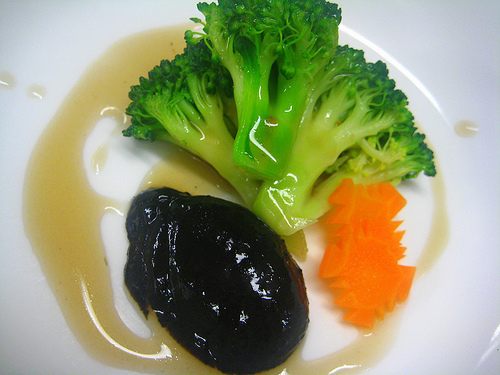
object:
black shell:
[123, 185, 308, 374]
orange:
[352, 217, 392, 284]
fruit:
[125, 187, 309, 375]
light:
[339, 21, 447, 120]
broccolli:
[120, 0, 435, 237]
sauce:
[453, 119, 480, 137]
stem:
[229, 81, 308, 183]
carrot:
[320, 178, 416, 332]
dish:
[0, 0, 500, 375]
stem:
[301, 132, 320, 199]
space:
[263, 59, 285, 106]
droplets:
[0, 71, 49, 103]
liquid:
[21, 21, 453, 375]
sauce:
[242, 111, 344, 226]